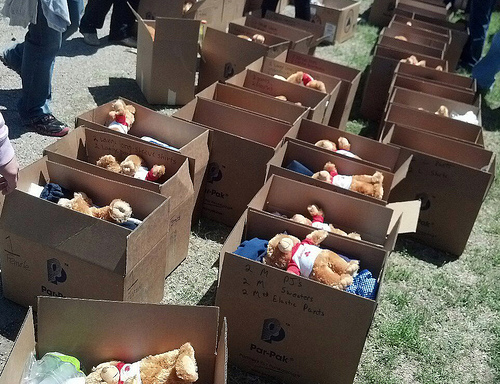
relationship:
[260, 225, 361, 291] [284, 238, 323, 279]
teddy bear wearing shirt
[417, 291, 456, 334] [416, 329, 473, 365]
grass on ground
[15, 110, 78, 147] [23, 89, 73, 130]
shoe on foot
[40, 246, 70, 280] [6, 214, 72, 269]
symbol on box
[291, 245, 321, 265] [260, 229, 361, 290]
shirt on teddy bear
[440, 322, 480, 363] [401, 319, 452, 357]
patches on grass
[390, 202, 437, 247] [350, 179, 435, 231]
flap of box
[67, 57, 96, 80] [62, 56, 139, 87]
gravel on ground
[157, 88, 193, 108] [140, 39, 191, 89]
tape on box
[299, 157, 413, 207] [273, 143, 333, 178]
teddy bear on box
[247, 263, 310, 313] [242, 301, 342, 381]
handwriting on box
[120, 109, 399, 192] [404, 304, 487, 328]
boxes on grass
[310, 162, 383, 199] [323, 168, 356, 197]
teddy bear wearing shirt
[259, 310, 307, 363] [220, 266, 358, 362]
logo on box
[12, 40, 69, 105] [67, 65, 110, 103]
person on grass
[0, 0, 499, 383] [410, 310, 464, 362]
grass on ground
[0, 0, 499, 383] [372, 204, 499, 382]
grass on ground